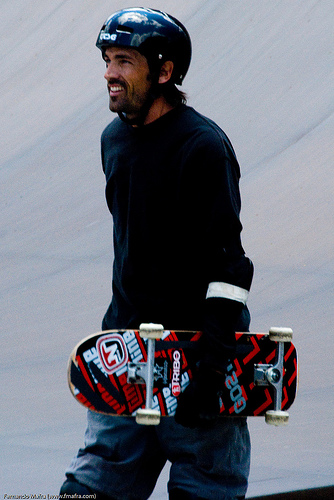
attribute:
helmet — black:
[96, 7, 191, 125]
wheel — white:
[139, 324, 166, 340]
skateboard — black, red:
[69, 322, 297, 425]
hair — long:
[161, 81, 188, 108]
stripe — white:
[204, 279, 249, 304]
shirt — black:
[101, 102, 254, 374]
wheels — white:
[135, 323, 293, 427]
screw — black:
[128, 377, 138, 385]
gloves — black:
[176, 366, 226, 431]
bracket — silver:
[127, 361, 147, 385]